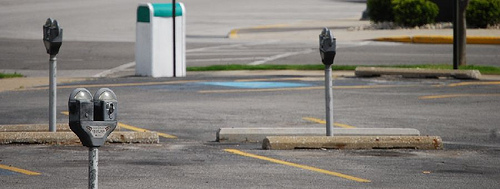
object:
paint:
[389, 34, 499, 43]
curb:
[375, 33, 500, 45]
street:
[8, 39, 492, 67]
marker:
[221, 147, 372, 181]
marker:
[302, 116, 357, 128]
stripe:
[225, 147, 374, 184]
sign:
[85, 126, 111, 139]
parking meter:
[62, 85, 118, 187]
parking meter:
[37, 17, 68, 129]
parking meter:
[313, 25, 342, 137]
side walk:
[206, 11, 430, 63]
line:
[223, 148, 373, 183]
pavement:
[0, 1, 497, 189]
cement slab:
[262, 134, 444, 151]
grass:
[218, 64, 260, 70]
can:
[132, 1, 187, 78]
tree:
[428, 0, 487, 67]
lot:
[1, 0, 500, 189]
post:
[320, 61, 339, 136]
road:
[1, 2, 495, 189]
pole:
[170, 1, 183, 79]